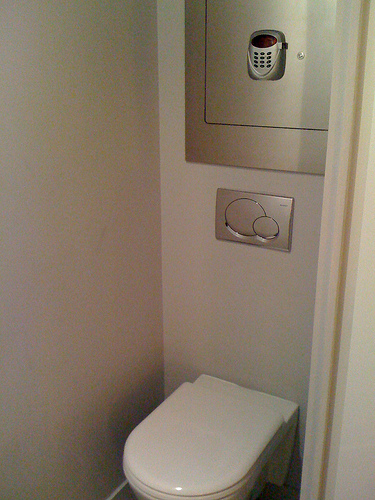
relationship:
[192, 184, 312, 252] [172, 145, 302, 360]
flush button on wall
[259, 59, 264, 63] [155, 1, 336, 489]
button on wall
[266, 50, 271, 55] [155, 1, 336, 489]
button on wall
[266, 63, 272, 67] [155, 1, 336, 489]
button on wall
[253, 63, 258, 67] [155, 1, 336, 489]
button on wall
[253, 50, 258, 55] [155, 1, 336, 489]
button on wall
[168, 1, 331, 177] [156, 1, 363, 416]
safe in wall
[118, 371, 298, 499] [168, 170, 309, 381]
toilet on wall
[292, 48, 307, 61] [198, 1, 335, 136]
circle on door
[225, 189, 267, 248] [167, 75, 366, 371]
plate on wall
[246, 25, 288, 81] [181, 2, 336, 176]
keypad on wall safe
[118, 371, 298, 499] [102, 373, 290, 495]
toilet with lid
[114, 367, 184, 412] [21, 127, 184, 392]
shadow on wall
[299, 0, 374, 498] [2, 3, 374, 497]
frame in bathroom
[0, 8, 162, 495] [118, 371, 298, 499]
wall beside toilet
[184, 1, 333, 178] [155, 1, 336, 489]
safe in wall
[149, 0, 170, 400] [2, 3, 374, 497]
corner in bathroom